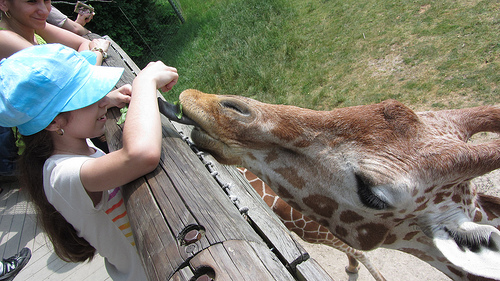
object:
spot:
[263, 150, 280, 164]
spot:
[275, 183, 295, 199]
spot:
[273, 166, 307, 190]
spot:
[337, 208, 363, 224]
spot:
[414, 194, 427, 204]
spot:
[452, 194, 461, 203]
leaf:
[172, 99, 184, 119]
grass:
[171, 0, 500, 106]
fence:
[77, 32, 334, 278]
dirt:
[364, 62, 402, 77]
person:
[2, 0, 110, 65]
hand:
[132, 60, 180, 91]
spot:
[433, 191, 446, 204]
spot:
[403, 230, 421, 241]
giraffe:
[236, 167, 390, 281]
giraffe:
[156, 89, 500, 281]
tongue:
[154, 95, 189, 125]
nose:
[98, 97, 111, 108]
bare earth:
[348, 52, 420, 89]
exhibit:
[78, 0, 499, 280]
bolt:
[192, 273, 214, 280]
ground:
[311, 236, 444, 279]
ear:
[44, 120, 60, 131]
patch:
[284, 0, 499, 100]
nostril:
[220, 100, 247, 115]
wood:
[115, 144, 289, 257]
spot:
[300, 193, 340, 219]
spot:
[354, 223, 389, 250]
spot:
[248, 179, 266, 199]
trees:
[107, 12, 263, 80]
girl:
[0, 43, 178, 281]